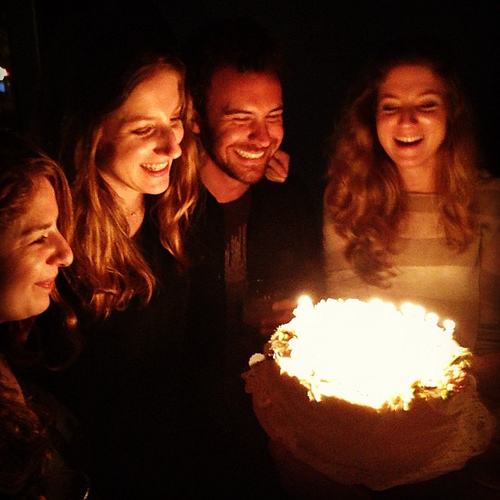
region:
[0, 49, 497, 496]
Four people around a birthday cake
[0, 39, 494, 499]
Four people celebrating a birthday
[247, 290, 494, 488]
Birthday cake with a lot of candles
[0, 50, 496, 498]
Four people smiling around a birthday cake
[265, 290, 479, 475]
Cake with bright birthday candles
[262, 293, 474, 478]
Candles lit on a cake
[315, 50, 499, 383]
Woman wearing a gray striped shirt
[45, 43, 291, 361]
Woman with her hand on a mans shoulder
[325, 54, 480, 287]
Long wavy blonde hair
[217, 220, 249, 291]
Design on a shirt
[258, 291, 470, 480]
birthday cake on table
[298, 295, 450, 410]
candles on birthday cake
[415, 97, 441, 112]
blond woman's left eye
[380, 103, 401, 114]
blonde woman's right eye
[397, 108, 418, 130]
the nose of the woman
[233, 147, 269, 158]
the man's white teeth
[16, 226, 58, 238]
the older woman's right eyebrow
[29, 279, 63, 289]
the older woman's lips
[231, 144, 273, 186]
the beard on the man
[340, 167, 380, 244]
woman with long curly hair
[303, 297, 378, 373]
bright candles on cake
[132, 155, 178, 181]
woman with smile on her face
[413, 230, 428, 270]
woman wearing plaid shirt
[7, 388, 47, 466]
woman wearing burgandy shirt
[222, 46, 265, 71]
man with black hair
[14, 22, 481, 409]
several faces around a birthday cake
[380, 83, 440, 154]
the face of a woman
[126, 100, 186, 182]
the face of a woman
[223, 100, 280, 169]
the face of a man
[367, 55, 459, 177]
the head of a woman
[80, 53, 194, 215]
the head of a woman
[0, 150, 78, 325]
the head of a woman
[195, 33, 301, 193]
the head of a man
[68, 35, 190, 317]
a woman with long hair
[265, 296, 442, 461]
A cake on the table.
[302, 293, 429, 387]
The top of the cake has light on it.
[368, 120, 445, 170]
The woman is smiling.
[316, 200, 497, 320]
The shirt has stripes.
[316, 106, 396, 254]
The woman has long hair.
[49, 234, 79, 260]
The lady nose is pointed.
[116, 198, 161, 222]
The woman is wearing a necklace.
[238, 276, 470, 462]
A cake with lots of candles on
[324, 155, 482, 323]
A woman with a gray and white sweater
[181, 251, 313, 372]
A man with a drink in his hand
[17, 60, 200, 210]
A woman with blonde hair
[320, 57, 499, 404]
woman wearing a striped a striped shirt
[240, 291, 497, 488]
doily under birthday cake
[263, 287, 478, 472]
birthday cale is illuminated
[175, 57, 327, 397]
man next to woman is smiling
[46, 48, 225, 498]
woman has long hair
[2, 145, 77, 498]
woman next to woman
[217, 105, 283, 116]
man has eyebrows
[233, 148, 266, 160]
teeth under nose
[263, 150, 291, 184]
hand next to face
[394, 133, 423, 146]
mouth is open